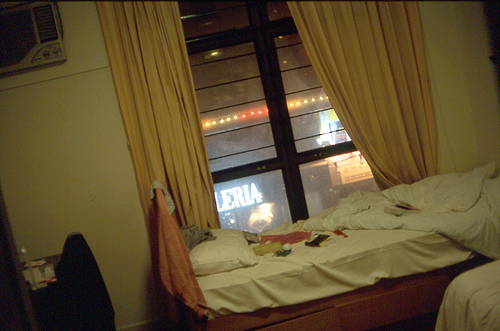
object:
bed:
[151, 162, 500, 329]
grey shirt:
[180, 224, 218, 251]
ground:
[441, 157, 458, 185]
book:
[305, 233, 335, 247]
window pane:
[210, 161, 313, 230]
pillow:
[186, 228, 258, 275]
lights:
[204, 95, 328, 127]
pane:
[183, 2, 389, 229]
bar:
[187, 37, 346, 159]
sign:
[213, 182, 264, 212]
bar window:
[180, 7, 371, 219]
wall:
[3, 0, 497, 298]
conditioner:
[1, 2, 68, 75]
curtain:
[93, 1, 220, 229]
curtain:
[287, 0, 439, 190]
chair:
[53, 231, 116, 329]